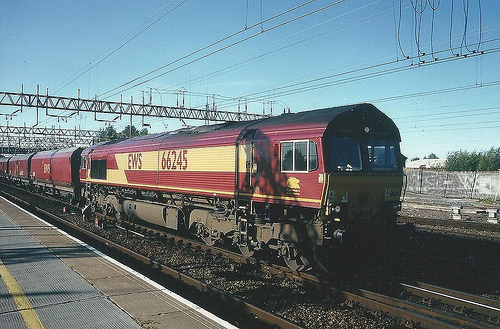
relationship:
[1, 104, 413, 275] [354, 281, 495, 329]
railroad car on track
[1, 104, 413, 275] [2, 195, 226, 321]
railroad car next to platform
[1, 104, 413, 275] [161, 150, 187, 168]
railroad car has numbers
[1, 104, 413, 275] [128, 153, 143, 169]
railroad car has letters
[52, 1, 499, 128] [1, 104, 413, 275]
wires are above railroad car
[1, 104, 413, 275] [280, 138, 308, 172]
railroad car has a window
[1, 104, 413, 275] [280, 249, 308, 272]
railroad car has wheels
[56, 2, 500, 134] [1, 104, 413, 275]
lines are above railroad car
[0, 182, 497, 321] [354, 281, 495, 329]
gravel next to track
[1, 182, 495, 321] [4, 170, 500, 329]
track at railway station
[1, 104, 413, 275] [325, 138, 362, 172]
railroad car has a window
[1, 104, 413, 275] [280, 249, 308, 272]
railroad car has a wheels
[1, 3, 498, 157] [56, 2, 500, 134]
sky has lines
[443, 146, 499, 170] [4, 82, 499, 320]
tree near railway station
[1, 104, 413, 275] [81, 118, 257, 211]
railroad car has an engine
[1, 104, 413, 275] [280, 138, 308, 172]
railroad car has window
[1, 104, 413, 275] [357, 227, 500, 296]
railroad car has a shadow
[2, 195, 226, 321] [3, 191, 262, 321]
platform has a shadow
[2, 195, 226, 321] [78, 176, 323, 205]
platform has a stripe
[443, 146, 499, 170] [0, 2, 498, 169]
tree in background